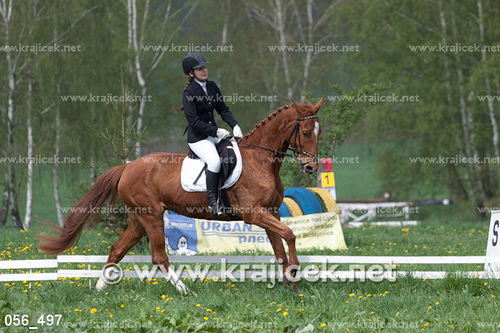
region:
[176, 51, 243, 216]
A woman riding on a horse.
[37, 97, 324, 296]
A large brown horse in a field.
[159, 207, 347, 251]
A sign with tires behind it.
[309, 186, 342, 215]
A yellow tire in a stack.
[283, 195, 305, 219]
A yellow tire in a stack.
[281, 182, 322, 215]
A blue tire in a stack.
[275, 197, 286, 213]
A blue tire in a stack.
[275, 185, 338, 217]
A pile of painted tires.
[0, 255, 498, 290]
A small section of white fence.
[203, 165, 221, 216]
A woman's black riding boot.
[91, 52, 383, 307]
a horse running outside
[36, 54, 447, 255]
a brown horse running outside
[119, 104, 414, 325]
a horse running in a field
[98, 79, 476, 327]
a brown horse running in a field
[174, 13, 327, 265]
a woman wearing a helmet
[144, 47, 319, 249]
a woman riding a horse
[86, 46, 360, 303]
a woman riding a brown horse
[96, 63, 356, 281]
a woman on a saddle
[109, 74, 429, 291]
a horse with a saddle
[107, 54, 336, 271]
a brown horse with saddle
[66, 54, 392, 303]
a woman riding a horse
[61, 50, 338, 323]
a woman riding a horse on the grass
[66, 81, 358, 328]
a brown and white horse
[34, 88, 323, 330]
a white and brown horse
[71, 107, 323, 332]
a horse walking on the grass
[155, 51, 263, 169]
a woman wearing a riding outfit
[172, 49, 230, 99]
a woman wearing a black helmet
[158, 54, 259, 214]
a woman wearing riding boots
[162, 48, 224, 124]
a woman wearing her hair in braids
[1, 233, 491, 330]
a white fence on the grass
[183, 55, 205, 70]
the helmet of the jockey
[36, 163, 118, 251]
the beautiful long tail of the horse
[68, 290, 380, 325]
many yellow flowers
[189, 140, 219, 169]
she wears a white pant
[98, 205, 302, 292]
the four legs of the horse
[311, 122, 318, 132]
a white spot on the horse's head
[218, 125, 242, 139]
a couple of white gloves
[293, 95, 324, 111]
the two ears of the horse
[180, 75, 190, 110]
she has a long hair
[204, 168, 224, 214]
a tall black boot